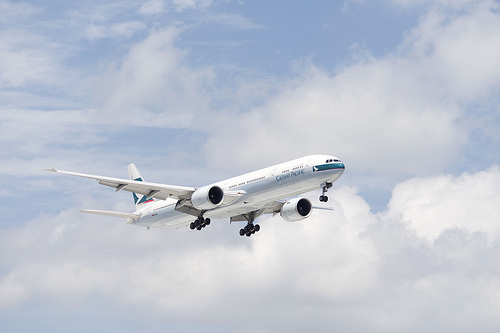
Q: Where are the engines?
A: On the wings.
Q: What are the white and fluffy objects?
A: Clouds.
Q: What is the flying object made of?
A: Metal.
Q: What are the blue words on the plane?
A: Airlines name.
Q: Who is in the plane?
A: Travelers.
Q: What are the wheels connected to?
A: Landing gear.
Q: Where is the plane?
A: In the sky.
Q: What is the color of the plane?
A: White.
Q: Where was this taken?
A: On the ground.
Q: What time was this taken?
A: Daytime.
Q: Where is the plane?
A: The sky.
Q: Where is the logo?
A: The tail.